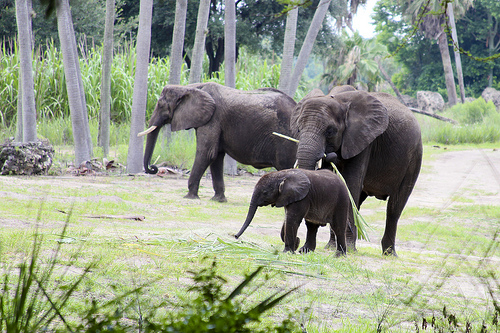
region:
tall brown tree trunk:
[13, 2, 42, 140]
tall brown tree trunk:
[14, 73, 24, 137]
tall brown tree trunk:
[51, 2, 94, 161]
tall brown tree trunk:
[99, 3, 111, 154]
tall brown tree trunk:
[126, 0, 150, 177]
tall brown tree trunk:
[170, 0, 185, 84]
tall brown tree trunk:
[191, 0, 213, 85]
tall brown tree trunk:
[222, 0, 236, 82]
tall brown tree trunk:
[280, 7, 294, 94]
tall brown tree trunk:
[291, 0, 330, 90]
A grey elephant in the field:
[230, 174, 360, 251]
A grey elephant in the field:
[269, 89, 431, 217]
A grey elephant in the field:
[163, 81, 273, 176]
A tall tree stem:
[61, 0, 90, 153]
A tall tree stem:
[13, 32, 48, 144]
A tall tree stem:
[52, 46, 99, 173]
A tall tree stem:
[280, 4, 294, 91]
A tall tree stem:
[295, 16, 321, 64]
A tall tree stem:
[433, 54, 468, 99]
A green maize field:
[31, 41, 72, 109]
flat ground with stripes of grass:
[5, 150, 492, 330]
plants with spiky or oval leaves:
[5, 195, 492, 325]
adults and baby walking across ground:
[140, 76, 425, 256]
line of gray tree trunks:
[5, 0, 332, 175]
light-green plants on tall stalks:
[0, 35, 280, 122]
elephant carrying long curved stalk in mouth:
[271, 101, 371, 241]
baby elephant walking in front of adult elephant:
[231, 91, 366, 251]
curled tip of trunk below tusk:
[132, 72, 167, 172]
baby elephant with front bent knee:
[226, 165, 351, 257]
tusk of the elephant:
[138, 123, 158, 135]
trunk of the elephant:
[227, 200, 257, 239]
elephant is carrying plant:
[280, 128, 367, 225]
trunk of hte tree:
[60, 101, 97, 171]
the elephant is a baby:
[228, 180, 362, 256]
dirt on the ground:
[439, 160, 479, 201]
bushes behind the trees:
[96, 47, 133, 132]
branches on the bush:
[422, 271, 464, 326]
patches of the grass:
[310, 292, 350, 312]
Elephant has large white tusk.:
[128, 124, 168, 142]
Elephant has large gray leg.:
[188, 141, 220, 218]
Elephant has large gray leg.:
[206, 161, 231, 200]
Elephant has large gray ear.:
[345, 96, 396, 149]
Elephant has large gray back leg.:
[376, 193, 409, 272]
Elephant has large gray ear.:
[283, 169, 306, 202]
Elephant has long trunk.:
[226, 205, 271, 248]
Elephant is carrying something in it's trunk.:
[133, 139, 173, 204]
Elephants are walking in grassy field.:
[165, 168, 420, 270]